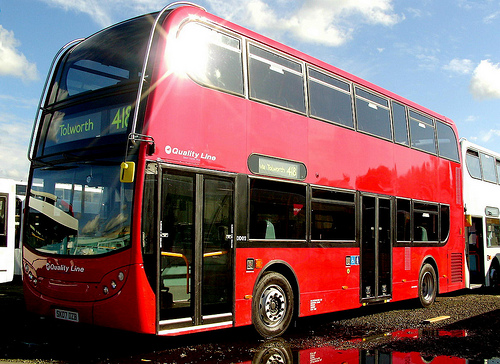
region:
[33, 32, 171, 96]
Small window on a bus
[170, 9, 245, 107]
Small window on a bus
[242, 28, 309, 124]
Small window on a bus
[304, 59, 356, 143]
Small window on a bus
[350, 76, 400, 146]
Small window on a bus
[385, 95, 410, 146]
Small window on a bus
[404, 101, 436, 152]
Small window on a bus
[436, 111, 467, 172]
Small window on a bus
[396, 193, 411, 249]
Small window on a bus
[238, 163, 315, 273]
Small window on a bus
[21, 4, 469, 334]
double decker red bus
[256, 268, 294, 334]
black tire on bus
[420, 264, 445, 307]
black rear tire on bus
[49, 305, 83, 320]
front license plate on bus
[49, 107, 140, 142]
the destination of the bus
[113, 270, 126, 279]
headlight on the bus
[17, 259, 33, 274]
headlight on right side of bus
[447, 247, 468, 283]
vent on side of the bus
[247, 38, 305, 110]
window on top deck of bus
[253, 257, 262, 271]
reflector on side of bus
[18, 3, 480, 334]
bus parked in lot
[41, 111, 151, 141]
sign on a bus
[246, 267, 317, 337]
tire on a bus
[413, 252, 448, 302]
tire on a bus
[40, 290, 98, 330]
license plate on bus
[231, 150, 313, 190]
sign on a bus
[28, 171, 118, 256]
window on a bus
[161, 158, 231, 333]
door on a bus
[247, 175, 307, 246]
window on a bus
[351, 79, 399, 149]
window on bus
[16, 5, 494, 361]
A bus is in a big city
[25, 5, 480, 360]
A bus is carrying many passengers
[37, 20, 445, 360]
A bus has several big windows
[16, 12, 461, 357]
A bus is painted bright red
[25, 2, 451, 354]
The bus is preparing to leave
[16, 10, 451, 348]
The bus is carrying many tourists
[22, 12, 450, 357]
The bus is operating very safely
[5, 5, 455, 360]
The bus is operating in the daytime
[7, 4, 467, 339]
A double decker bus.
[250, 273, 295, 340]
The bus's tire.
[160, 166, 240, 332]
The buses front door.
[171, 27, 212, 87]
The sun glaring off the bus.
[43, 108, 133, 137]
The bus's route and bus number.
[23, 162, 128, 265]
The bus's windshield.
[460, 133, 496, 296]
Another bus lined up.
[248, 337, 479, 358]
A water puddle after the rain.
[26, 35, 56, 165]
Handles on the bus.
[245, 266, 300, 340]
a tire on a bus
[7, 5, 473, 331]
a double decker red bus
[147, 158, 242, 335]
doors of a bus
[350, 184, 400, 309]
doors of a bus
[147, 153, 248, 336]
doors of a bus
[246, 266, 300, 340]
black rubber tire with silver hub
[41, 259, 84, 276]
white emblazoned letters on red reading Quality Line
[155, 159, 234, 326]
shiny double door for bus entry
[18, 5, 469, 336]
large red double decker bus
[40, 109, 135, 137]
yellow-green LEDs indicating bus's destiation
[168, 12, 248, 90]
sunlight reflecting brightly on bus window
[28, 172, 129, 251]
highly polished bus window reflecting background objects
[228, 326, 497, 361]
large puddle of water on asphalt reflecting bus